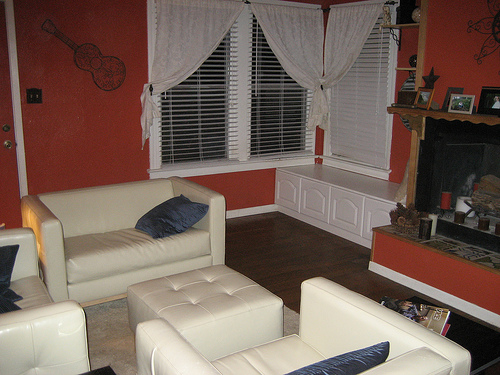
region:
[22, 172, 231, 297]
a white leather love seat is in the room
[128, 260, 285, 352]
a tufted ottoman is in the center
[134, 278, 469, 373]
a white chair has a blue pillow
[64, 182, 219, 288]
a blue pillow is on the love seat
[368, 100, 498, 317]
a fireplace is in the living room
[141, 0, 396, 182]
white curtains are on the corner windows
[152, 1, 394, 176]
blinds are on the windows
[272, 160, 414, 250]
a window seat is under the window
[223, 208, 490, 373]
the wooden floors are dark brown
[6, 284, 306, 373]
a cream carpet is on the floor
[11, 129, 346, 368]
the furniture is white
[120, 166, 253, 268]
the pillow is blue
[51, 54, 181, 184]
the walls are red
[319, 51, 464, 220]
pictures on the fireplace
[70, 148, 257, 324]
the material is white leather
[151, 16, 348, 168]
white curtains and blinds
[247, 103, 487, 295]
a window box seat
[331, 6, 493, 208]
this is a fireplace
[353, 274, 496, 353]
magazines on the table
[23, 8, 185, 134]
a wall decoration shaped like a guitar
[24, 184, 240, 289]
a small white leather love seat with a blue pillow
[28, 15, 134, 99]
a guitar piece of art on the wall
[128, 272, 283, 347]
a white square leather ottoman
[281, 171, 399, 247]
a white built-in cabinet under the window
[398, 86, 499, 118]
several picture frames on the shelf above the fireplace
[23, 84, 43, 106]
a black light switch on the wall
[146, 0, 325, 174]
a window with white curtains and mini-blinds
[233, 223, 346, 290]
dark hardwood floors near the window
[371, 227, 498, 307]
a fireplace mantle made of tile on the top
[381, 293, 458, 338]
a few magazines on a small table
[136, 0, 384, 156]
three white curtains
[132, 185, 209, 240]
a blue throw pillow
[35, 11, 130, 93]
a guitar shaped wall art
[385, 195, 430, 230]
a bowl of pinecones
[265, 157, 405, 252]
a white window seat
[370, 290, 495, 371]
a black side table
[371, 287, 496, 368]
magazines on side table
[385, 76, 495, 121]
pictures on fireplace mantle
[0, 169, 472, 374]
four pieces of upholstered furniture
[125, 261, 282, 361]
a white footstool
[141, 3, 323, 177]
the living room has white curtains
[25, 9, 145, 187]
the wall of living room is red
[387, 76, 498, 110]
pictures over a shelf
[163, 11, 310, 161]
blinds that cover a window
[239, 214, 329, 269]
the floor of a room is wood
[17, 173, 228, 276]
the couch in living room is white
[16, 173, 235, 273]
the couch in made of white lether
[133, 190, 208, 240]
a blue pillow on a white couch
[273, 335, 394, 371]
pillow on a chair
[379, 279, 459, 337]
magazines on a side table